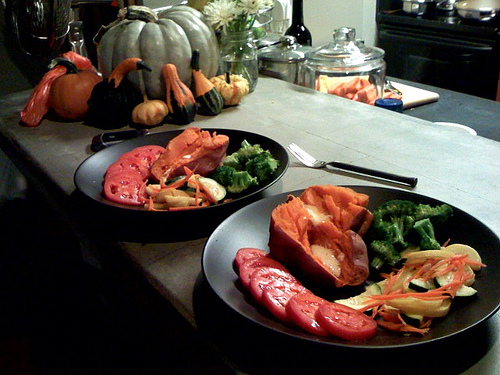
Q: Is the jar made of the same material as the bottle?
A: Yes, both the jar and the bottle are made of glass.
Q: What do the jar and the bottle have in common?
A: The material, both the jar and the bottle are glass.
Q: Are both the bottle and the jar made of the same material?
A: Yes, both the bottle and the jar are made of glass.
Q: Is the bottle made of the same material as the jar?
A: Yes, both the bottle and the jar are made of glass.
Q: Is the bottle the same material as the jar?
A: Yes, both the bottle and the jar are made of glass.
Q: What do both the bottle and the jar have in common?
A: The material, both the bottle and the jar are glass.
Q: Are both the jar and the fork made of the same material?
A: No, the jar is made of glass and the fork is made of metal.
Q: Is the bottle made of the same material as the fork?
A: No, the bottle is made of glass and the fork is made of metal.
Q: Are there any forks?
A: Yes, there is a fork.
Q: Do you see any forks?
A: Yes, there is a fork.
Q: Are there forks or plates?
A: Yes, there is a fork.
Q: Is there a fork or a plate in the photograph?
A: Yes, there is a fork.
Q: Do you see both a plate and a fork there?
A: Yes, there are both a fork and a plate.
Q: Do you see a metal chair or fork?
A: Yes, there is a metal fork.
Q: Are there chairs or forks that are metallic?
A: Yes, the fork is metallic.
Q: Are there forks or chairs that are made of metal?
A: Yes, the fork is made of metal.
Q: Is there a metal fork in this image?
A: Yes, there is a metal fork.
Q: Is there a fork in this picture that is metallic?
A: Yes, there is a fork that is metallic.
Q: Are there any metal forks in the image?
A: Yes, there is a fork that is made of metal.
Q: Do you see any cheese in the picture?
A: No, there is no cheese.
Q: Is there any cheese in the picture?
A: No, there is no cheese.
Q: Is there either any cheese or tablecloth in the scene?
A: No, there are no cheese or tablecloths.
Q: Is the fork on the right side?
A: Yes, the fork is on the right of the image.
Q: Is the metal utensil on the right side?
A: Yes, the fork is on the right of the image.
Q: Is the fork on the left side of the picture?
A: No, the fork is on the right of the image.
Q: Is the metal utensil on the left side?
A: No, the fork is on the right of the image.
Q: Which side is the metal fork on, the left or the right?
A: The fork is on the right of the image.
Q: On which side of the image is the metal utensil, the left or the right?
A: The fork is on the right of the image.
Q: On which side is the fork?
A: The fork is on the right of the image.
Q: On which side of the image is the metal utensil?
A: The fork is on the right of the image.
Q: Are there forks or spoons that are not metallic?
A: No, there is a fork but it is metallic.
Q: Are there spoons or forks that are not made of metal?
A: No, there is a fork but it is made of metal.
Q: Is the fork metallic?
A: Yes, the fork is metallic.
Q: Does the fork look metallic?
A: Yes, the fork is metallic.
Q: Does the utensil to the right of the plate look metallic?
A: Yes, the fork is metallic.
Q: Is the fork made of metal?
A: Yes, the fork is made of metal.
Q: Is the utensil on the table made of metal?
A: Yes, the fork is made of metal.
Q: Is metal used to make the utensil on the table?
A: Yes, the fork is made of metal.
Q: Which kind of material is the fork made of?
A: The fork is made of metal.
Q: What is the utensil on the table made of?
A: The fork is made of metal.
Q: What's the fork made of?
A: The fork is made of metal.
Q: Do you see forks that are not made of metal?
A: No, there is a fork but it is made of metal.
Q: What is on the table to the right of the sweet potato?
A: The fork is on the table.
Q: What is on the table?
A: The fork is on the table.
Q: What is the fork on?
A: The fork is on the table.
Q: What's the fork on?
A: The fork is on the table.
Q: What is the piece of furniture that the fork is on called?
A: The piece of furniture is a table.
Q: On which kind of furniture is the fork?
A: The fork is on the table.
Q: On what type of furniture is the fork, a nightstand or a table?
A: The fork is on a table.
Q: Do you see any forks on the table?
A: Yes, there is a fork on the table.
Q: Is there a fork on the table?
A: Yes, there is a fork on the table.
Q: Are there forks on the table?
A: Yes, there is a fork on the table.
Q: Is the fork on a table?
A: Yes, the fork is on a table.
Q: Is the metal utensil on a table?
A: Yes, the fork is on a table.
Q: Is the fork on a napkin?
A: No, the fork is on a table.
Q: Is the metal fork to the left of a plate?
A: No, the fork is to the right of a plate.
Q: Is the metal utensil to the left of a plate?
A: No, the fork is to the right of a plate.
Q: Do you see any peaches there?
A: No, there are no peaches.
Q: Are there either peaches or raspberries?
A: No, there are no peaches or raspberries.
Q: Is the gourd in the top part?
A: Yes, the gourd is in the top of the image.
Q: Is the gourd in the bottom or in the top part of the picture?
A: The gourd is in the top of the image.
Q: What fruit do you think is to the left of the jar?
A: The fruit is a gourd.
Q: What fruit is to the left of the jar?
A: The fruit is a gourd.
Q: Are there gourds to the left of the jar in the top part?
A: Yes, there is a gourd to the left of the jar.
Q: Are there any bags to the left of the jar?
A: No, there is a gourd to the left of the jar.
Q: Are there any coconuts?
A: No, there are no coconuts.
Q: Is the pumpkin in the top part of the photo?
A: Yes, the pumpkin is in the top of the image.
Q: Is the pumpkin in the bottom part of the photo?
A: No, the pumpkin is in the top of the image.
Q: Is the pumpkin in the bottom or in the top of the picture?
A: The pumpkin is in the top of the image.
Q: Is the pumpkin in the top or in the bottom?
A: The pumpkin is in the top of the image.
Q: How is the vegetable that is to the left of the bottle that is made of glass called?
A: The vegetable is a pumpkin.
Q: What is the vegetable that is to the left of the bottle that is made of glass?
A: The vegetable is a pumpkin.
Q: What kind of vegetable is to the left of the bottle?
A: The vegetable is a pumpkin.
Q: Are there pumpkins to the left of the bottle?
A: Yes, there is a pumpkin to the left of the bottle.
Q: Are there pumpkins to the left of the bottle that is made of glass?
A: Yes, there is a pumpkin to the left of the bottle.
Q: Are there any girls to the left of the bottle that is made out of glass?
A: No, there is a pumpkin to the left of the bottle.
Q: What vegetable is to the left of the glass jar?
A: The vegetable is a pumpkin.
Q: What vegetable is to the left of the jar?
A: The vegetable is a pumpkin.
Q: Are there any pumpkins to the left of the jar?
A: Yes, there is a pumpkin to the left of the jar.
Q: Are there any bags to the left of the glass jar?
A: No, there is a pumpkin to the left of the jar.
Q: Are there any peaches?
A: No, there are no peaches.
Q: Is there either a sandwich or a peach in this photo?
A: No, there are no peaches or sandwiches.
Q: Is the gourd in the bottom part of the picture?
A: No, the gourd is in the top of the image.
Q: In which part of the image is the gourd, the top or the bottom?
A: The gourd is in the top of the image.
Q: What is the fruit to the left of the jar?
A: The fruit is a gourd.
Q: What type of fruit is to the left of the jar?
A: The fruit is a gourd.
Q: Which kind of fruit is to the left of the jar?
A: The fruit is a gourd.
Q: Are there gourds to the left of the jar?
A: Yes, there is a gourd to the left of the jar.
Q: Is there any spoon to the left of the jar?
A: No, there is a gourd to the left of the jar.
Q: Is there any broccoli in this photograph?
A: Yes, there is broccoli.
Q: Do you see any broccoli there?
A: Yes, there is broccoli.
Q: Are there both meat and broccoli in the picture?
A: No, there is broccoli but no meat.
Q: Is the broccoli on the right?
A: Yes, the broccoli is on the right of the image.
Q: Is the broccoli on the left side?
A: No, the broccoli is on the right of the image.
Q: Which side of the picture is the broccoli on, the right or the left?
A: The broccoli is on the right of the image.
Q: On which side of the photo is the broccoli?
A: The broccoli is on the right of the image.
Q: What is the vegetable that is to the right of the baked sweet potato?
A: The vegetable is broccoli.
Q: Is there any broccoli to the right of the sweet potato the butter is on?
A: Yes, there is broccoli to the right of the sweet potato.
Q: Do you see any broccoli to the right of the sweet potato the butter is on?
A: Yes, there is broccoli to the right of the sweet potato.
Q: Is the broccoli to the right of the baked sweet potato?
A: Yes, the broccoli is to the right of the sweet potato.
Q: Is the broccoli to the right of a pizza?
A: No, the broccoli is to the right of the sweet potato.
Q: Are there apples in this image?
A: No, there are no apples.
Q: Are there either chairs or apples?
A: No, there are no apples or chairs.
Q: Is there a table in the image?
A: Yes, there is a table.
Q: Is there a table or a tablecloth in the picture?
A: Yes, there is a table.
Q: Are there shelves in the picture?
A: No, there are no shelves.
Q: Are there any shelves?
A: No, there are no shelves.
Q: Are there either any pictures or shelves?
A: No, there are no shelves or pictures.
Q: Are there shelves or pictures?
A: No, there are no shelves or pictures.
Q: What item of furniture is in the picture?
A: The piece of furniture is a table.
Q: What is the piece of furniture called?
A: The piece of furniture is a table.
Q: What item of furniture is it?
A: The piece of furniture is a table.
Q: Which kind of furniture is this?
A: This is a table.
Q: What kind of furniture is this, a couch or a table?
A: This is a table.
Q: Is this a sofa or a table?
A: This is a table.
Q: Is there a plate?
A: Yes, there is a plate.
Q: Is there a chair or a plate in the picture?
A: Yes, there is a plate.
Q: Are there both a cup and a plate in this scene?
A: No, there is a plate but no cups.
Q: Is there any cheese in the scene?
A: No, there is no cheese.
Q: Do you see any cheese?
A: No, there is no cheese.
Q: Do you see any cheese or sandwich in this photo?
A: No, there are no cheese or sandwiches.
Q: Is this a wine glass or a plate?
A: This is a plate.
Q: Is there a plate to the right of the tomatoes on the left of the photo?
A: Yes, there is a plate to the right of the tomatoes.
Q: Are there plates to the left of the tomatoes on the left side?
A: No, the plate is to the right of the tomatoes.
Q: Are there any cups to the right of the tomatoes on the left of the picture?
A: No, there is a plate to the right of the tomatoes.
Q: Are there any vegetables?
A: Yes, there are vegetables.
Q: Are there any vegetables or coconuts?
A: Yes, there are vegetables.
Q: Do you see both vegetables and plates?
A: Yes, there are both vegetables and a plate.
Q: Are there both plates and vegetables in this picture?
A: Yes, there are both vegetables and a plate.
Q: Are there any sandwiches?
A: No, there are no sandwiches.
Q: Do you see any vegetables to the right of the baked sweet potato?
A: Yes, there are vegetables to the right of the sweet potato.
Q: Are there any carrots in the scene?
A: Yes, there is a carrot.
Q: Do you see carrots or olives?
A: Yes, there is a carrot.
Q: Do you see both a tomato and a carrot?
A: Yes, there are both a carrot and a tomato.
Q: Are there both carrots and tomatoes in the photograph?
A: Yes, there are both a carrot and a tomato.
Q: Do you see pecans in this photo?
A: No, there are no pecans.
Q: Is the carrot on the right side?
A: Yes, the carrot is on the right of the image.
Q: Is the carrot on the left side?
A: No, the carrot is on the right of the image.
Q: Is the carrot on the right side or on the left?
A: The carrot is on the right of the image.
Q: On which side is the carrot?
A: The carrot is on the right of the image.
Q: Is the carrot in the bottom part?
A: Yes, the carrot is in the bottom of the image.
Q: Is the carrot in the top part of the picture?
A: No, the carrot is in the bottom of the image.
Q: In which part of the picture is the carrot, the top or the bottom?
A: The carrot is in the bottom of the image.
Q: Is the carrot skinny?
A: Yes, the carrot is skinny.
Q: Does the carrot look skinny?
A: Yes, the carrot is skinny.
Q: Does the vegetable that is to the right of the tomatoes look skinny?
A: Yes, the carrot is skinny.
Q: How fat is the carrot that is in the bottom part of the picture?
A: The carrot is skinny.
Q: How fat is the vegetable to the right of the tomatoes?
A: The carrot is skinny.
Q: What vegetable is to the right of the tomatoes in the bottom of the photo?
A: The vegetable is a carrot.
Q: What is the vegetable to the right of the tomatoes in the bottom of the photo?
A: The vegetable is a carrot.